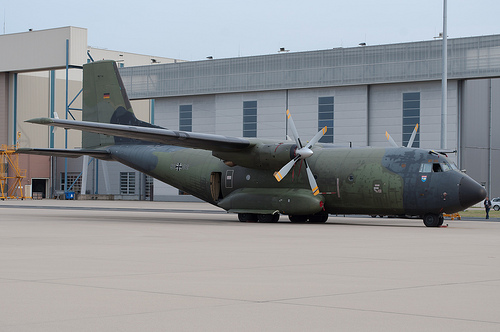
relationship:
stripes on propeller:
[273, 108, 333, 198] [269, 100, 349, 232]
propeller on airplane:
[271, 109, 328, 196] [17, 60, 487, 227]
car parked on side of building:
[486, 192, 498, 204] [110, 31, 499, 203]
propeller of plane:
[271, 109, 328, 196] [11, 58, 486, 226]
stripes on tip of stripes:
[310, 182, 322, 194] [272, 171, 282, 181]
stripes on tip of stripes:
[310, 182, 322, 194] [285, 107, 292, 119]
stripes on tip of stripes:
[310, 182, 322, 194] [321, 123, 327, 133]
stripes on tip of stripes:
[310, 182, 322, 194] [413, 120, 420, 132]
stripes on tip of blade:
[310, 182, 322, 194] [303, 156, 320, 196]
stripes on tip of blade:
[310, 182, 322, 194] [273, 153, 299, 180]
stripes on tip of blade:
[310, 182, 322, 194] [285, 108, 302, 146]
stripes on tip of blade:
[310, 182, 322, 194] [303, 125, 327, 147]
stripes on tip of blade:
[310, 182, 322, 194] [406, 121, 420, 144]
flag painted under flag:
[420, 172, 427, 181] [98, 92, 113, 97]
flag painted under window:
[420, 172, 427, 181] [420, 161, 454, 172]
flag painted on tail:
[99, 90, 116, 106] [57, 52, 152, 154]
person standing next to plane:
[482, 192, 492, 222] [11, 58, 486, 226]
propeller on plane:
[383, 130, 398, 145] [11, 58, 486, 226]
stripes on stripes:
[380, 122, 392, 146] [318, 123, 330, 139]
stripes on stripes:
[380, 122, 392, 146] [279, 105, 299, 131]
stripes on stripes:
[380, 122, 392, 146] [305, 175, 321, 200]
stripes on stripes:
[380, 122, 392, 146] [265, 156, 287, 186]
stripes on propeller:
[380, 122, 392, 146] [379, 111, 436, 158]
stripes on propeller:
[380, 122, 392, 146] [265, 97, 337, 204]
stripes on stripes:
[272, 171, 282, 181] [312, 185, 322, 196]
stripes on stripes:
[272, 171, 282, 181] [285, 109, 294, 123]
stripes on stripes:
[272, 171, 282, 181] [322, 123, 331, 135]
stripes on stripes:
[272, 171, 282, 181] [384, 128, 397, 143]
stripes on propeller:
[272, 171, 282, 181] [271, 109, 328, 196]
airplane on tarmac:
[17, 60, 487, 227] [1, 200, 498, 329]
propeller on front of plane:
[263, 99, 340, 225] [11, 58, 486, 226]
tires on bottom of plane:
[212, 173, 464, 243] [58, 80, 490, 247]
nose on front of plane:
[462, 172, 486, 209] [11, 58, 486, 226]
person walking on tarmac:
[482, 196, 492, 219] [1, 200, 498, 329]